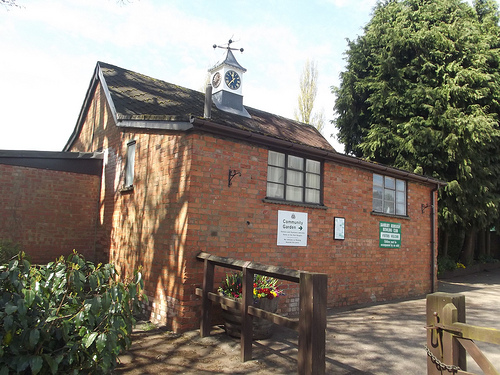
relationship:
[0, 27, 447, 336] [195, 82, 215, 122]
brick building has chimney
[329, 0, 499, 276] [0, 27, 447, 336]
tree behind brick building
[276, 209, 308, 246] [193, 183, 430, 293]
signs near building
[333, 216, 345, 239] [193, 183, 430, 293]
signs near building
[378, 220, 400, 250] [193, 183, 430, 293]
signs near building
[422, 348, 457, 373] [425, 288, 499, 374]
chain on gate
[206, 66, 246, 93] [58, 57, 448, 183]
clock in roof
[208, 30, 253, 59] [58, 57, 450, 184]
vane on roof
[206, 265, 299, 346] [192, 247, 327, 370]
box behind fence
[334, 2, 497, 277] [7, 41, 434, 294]
tree near house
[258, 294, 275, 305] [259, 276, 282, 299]
vase has flowers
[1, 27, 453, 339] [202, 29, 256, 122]
brick building with clock tower